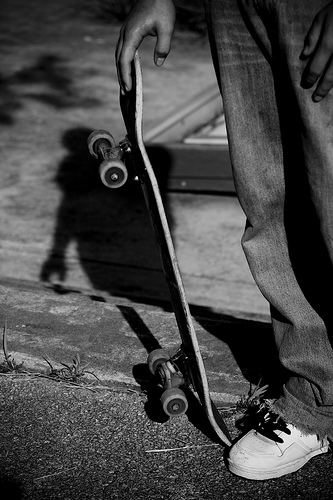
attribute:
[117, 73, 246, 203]
railing — wooden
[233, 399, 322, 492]
shoes — white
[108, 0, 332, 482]
man — skateboard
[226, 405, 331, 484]
shoe — man's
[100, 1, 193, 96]
hand — person's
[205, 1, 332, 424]
pant leg — man's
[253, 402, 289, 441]
shoelaces — black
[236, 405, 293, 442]
shoelaces — black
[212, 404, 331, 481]
shoes — white, man's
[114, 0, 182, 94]
hand — man's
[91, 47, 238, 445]
skateboard — older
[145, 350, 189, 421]
wheel — skateboard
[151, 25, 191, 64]
thumb — man's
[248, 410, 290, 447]
lace — black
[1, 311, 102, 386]
plants — small 